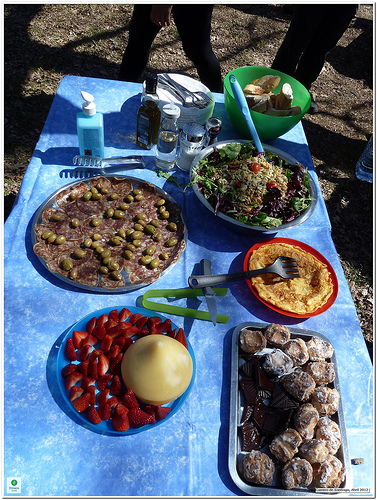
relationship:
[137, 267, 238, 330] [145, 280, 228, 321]
tongs were green